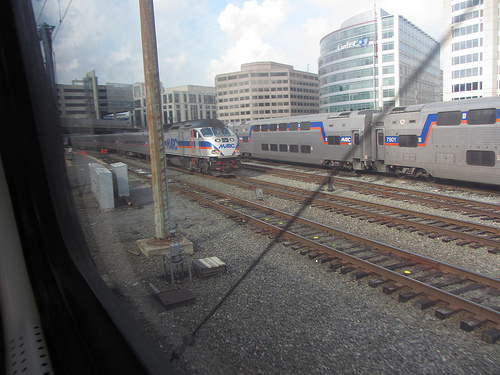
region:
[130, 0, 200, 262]
gray metal pole next to train tracks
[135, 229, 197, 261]
light gray concrete base supporting pole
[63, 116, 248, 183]
silver train with blue and red stripe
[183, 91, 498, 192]
gray train with blue and red stripe on it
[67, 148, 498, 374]
dark gray gravel underneath train tracks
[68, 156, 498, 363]
brown metal train tracks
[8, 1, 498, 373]
clear glass window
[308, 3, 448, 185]
silver and gray building near train tracks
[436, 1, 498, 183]
white building near train tracks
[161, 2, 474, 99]
thick puffy white clouds in the sky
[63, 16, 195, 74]
Sky is blue color.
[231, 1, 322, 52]
Clouds are white color.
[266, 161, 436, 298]
Tracks are brown color.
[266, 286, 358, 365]
gravel is grey color.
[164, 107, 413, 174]
Two trains are in track.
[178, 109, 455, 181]
Train are mainly grey color.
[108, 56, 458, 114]
Buildings are seen behind the train.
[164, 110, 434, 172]
lines in train are red and blue color.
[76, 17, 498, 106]
Buildings are white color.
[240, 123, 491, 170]
Windows are attached to the sides of the train.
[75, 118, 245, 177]
The train that has its engine shown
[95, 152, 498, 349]
The empty track on the left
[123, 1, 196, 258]
The pole whose vase is fully shown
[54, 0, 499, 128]
The buildings behind the trains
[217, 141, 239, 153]
The blue writing on the front of the train engine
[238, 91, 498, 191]
The double decker train cars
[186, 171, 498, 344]
The empty tracks in front of the train engine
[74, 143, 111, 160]
The cones around the empty train track on the left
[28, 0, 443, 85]
The clouds over the buildings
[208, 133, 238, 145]
The black writing of the train engine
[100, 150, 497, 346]
a set of train tracks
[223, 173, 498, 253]
a set of train tracks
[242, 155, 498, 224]
a set of train tracks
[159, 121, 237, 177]
a silver blue and red train engine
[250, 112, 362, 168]
a silver blue and red passenger train car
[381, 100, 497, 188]
a silver blue and red passenger train car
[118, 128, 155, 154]
a silver blue and red passenger train car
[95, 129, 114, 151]
a silver blue and red passenger train car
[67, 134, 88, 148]
a silver blue and red passenger train car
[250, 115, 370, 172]
a double decker passenger car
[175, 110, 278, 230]
The train has a sleek design.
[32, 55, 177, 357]
Looking out the window of a train.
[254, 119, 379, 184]
The train is silver, blue, and orange.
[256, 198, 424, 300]
Yellow dots are in between the two track rails.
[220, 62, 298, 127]
The building has multiple windows.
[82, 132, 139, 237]
Electrical boxes are on the ground.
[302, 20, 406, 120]
The building's windows curve.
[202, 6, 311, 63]
White clouds are in the sky.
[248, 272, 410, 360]
The ground is covered in gravel.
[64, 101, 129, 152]
A train tunnel is in the background.